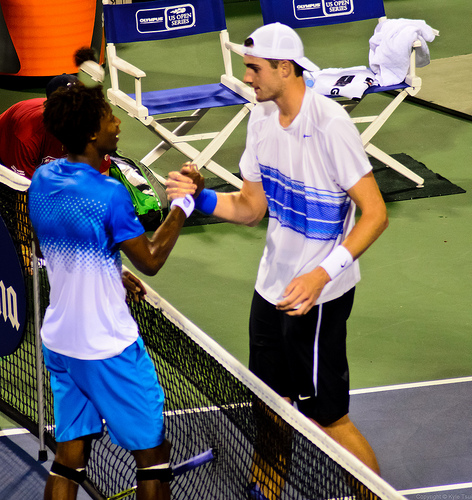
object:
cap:
[241, 22, 320, 72]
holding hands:
[165, 161, 206, 201]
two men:
[25, 20, 389, 497]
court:
[1, 1, 471, 497]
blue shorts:
[41, 332, 165, 452]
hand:
[179, 161, 205, 203]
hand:
[164, 171, 198, 202]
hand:
[270, 267, 336, 316]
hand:
[117, 269, 147, 303]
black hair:
[42, 85, 106, 151]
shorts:
[248, 283, 355, 427]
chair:
[107, 30, 288, 228]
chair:
[207, 16, 440, 189]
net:
[96, 285, 406, 499]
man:
[164, 20, 387, 498]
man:
[25, 81, 205, 498]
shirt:
[238, 85, 373, 309]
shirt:
[27, 160, 145, 360]